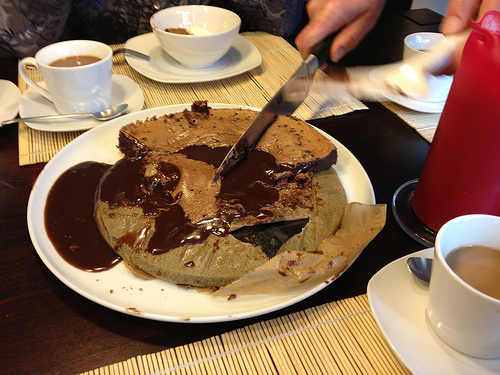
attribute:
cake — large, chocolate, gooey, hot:
[93, 101, 348, 289]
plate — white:
[26, 102, 378, 325]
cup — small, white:
[19, 39, 114, 116]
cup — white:
[426, 214, 500, 362]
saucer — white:
[17, 73, 147, 133]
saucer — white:
[366, 247, 498, 375]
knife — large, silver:
[212, 35, 339, 187]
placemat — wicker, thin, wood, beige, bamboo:
[15, 27, 369, 168]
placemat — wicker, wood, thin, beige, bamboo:
[80, 293, 414, 374]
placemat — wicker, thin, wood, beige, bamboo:
[344, 62, 453, 145]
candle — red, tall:
[411, 12, 499, 233]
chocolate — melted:
[44, 144, 320, 273]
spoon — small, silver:
[1, 103, 129, 125]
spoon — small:
[406, 257, 434, 284]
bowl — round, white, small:
[150, 5, 241, 69]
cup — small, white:
[403, 32, 452, 100]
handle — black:
[311, 34, 338, 67]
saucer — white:
[369, 60, 455, 114]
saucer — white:
[123, 31, 264, 84]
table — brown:
[0, 7, 499, 374]